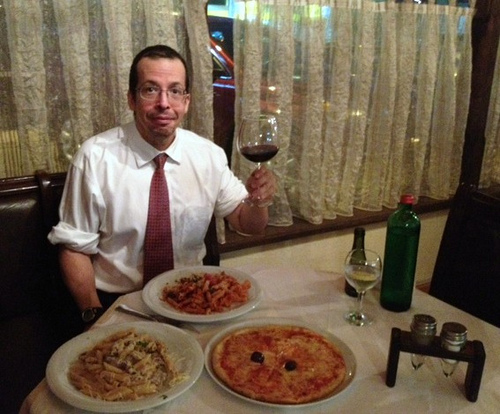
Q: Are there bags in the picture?
A: No, there are no bags.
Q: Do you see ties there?
A: Yes, there is a tie.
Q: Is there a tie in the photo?
A: Yes, there is a tie.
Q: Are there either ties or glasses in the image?
A: Yes, there is a tie.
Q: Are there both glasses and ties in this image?
A: Yes, there are both a tie and glasses.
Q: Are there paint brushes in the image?
A: No, there are no paint brushes.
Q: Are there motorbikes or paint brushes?
A: No, there are no paint brushes or motorbikes.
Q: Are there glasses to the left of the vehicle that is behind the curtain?
A: Yes, there are glasses to the left of the car.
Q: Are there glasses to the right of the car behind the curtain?
A: No, the glasses are to the left of the car.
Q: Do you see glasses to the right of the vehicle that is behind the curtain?
A: No, the glasses are to the left of the car.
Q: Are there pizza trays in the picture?
A: No, there are no pizza trays.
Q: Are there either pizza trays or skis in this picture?
A: No, there are no pizza trays or skis.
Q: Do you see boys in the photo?
A: No, there are no boys.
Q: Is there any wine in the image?
A: Yes, there is wine.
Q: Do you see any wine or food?
A: Yes, there is wine.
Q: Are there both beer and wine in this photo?
A: No, there is wine but no beer.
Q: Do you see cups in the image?
A: No, there are no cups.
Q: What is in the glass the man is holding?
A: The wine is in the glass.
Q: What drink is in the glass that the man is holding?
A: The drink is wine.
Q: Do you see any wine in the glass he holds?
A: Yes, there is wine in the glass.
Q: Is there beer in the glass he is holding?
A: No, there is wine in the glass.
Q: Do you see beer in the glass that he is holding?
A: No, there is wine in the glass.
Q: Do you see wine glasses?
A: Yes, there is a wine glass.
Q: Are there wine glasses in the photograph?
A: Yes, there is a wine glass.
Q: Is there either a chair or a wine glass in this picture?
A: Yes, there is a wine glass.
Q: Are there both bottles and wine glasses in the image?
A: Yes, there are both a wine glass and a bottle.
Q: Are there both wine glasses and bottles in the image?
A: Yes, there are both a wine glass and a bottle.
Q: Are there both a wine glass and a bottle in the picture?
A: Yes, there are both a wine glass and a bottle.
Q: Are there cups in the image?
A: No, there are no cups.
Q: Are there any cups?
A: No, there are no cups.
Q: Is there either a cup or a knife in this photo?
A: No, there are no cups or knives.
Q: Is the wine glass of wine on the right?
A: Yes, the wineglass is on the right of the image.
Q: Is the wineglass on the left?
A: No, the wineglass is on the right of the image.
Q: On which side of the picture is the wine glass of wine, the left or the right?
A: The wine glass is on the right of the image.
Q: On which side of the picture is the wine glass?
A: The wine glass is on the right of the image.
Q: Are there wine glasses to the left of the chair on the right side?
A: Yes, there is a wine glass to the left of the chair.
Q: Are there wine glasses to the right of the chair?
A: No, the wine glass is to the left of the chair.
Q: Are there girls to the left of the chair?
A: No, there is a wine glass to the left of the chair.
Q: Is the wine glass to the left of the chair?
A: Yes, the wine glass is to the left of the chair.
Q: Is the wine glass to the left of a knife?
A: No, the wine glass is to the left of the chair.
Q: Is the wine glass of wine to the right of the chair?
A: No, the wine glass is to the left of the chair.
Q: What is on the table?
A: The wine glass is on the table.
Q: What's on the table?
A: The wine glass is on the table.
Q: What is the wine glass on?
A: The wine glass is on the table.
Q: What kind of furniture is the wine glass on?
A: The wine glass is on the table.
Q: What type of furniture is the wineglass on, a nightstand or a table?
A: The wineglass is on a table.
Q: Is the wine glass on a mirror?
A: No, the wine glass is on the table.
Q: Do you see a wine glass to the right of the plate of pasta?
A: Yes, there is a wine glass to the right of the plate.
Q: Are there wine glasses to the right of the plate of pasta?
A: Yes, there is a wine glass to the right of the plate.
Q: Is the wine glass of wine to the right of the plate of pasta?
A: Yes, the wine glass is to the right of the plate.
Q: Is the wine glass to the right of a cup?
A: No, the wine glass is to the right of the plate.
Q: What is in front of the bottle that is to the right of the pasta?
A: The wine glass is in front of the bottle.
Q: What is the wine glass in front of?
A: The wine glass is in front of the bottle.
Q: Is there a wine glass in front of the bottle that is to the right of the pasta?
A: Yes, there is a wine glass in front of the bottle.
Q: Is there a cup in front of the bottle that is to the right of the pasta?
A: No, there is a wine glass in front of the bottle.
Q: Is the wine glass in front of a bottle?
A: Yes, the wine glass is in front of a bottle.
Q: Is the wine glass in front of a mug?
A: No, the wine glass is in front of a bottle.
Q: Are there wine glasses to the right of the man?
A: Yes, there is a wine glass to the right of the man.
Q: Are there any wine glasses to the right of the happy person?
A: Yes, there is a wine glass to the right of the man.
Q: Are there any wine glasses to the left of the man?
A: No, the wine glass is to the right of the man.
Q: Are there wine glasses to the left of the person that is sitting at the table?
A: No, the wine glass is to the right of the man.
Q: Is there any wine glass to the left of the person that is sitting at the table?
A: No, the wine glass is to the right of the man.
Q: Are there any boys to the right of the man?
A: No, there is a wine glass to the right of the man.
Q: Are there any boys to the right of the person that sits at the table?
A: No, there is a wine glass to the right of the man.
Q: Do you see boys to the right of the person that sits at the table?
A: No, there is a wine glass to the right of the man.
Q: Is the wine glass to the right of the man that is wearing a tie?
A: Yes, the wine glass is to the right of the man.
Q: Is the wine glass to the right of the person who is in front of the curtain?
A: Yes, the wine glass is to the right of the man.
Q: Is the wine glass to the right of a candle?
A: No, the wine glass is to the right of the man.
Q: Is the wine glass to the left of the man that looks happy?
A: No, the wine glass is to the right of the man.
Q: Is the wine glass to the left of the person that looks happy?
A: No, the wine glass is to the right of the man.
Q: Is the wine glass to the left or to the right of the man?
A: The wine glass is to the right of the man.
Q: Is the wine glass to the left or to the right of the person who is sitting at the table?
A: The wine glass is to the right of the man.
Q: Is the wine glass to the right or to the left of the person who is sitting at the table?
A: The wine glass is to the right of the man.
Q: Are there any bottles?
A: Yes, there is a bottle.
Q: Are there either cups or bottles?
A: Yes, there is a bottle.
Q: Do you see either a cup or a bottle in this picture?
A: Yes, there is a bottle.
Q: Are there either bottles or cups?
A: Yes, there is a bottle.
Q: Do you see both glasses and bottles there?
A: Yes, there are both a bottle and glasses.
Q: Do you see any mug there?
A: No, there are no mugs.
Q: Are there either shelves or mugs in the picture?
A: No, there are no mugs or shelves.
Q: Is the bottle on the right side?
A: Yes, the bottle is on the right of the image.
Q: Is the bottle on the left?
A: No, the bottle is on the right of the image.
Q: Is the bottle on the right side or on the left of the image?
A: The bottle is on the right of the image.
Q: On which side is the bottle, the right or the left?
A: The bottle is on the right of the image.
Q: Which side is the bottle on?
A: The bottle is on the right of the image.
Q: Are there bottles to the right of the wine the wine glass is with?
A: Yes, there is a bottle to the right of the wine.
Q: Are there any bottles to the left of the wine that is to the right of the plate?
A: No, the bottle is to the right of the wine.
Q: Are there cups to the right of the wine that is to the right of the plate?
A: No, there is a bottle to the right of the wine.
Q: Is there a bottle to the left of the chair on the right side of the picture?
A: Yes, there is a bottle to the left of the chair.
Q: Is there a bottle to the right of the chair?
A: No, the bottle is to the left of the chair.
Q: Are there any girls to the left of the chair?
A: No, there is a bottle to the left of the chair.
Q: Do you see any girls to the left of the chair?
A: No, there is a bottle to the left of the chair.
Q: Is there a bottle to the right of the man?
A: Yes, there is a bottle to the right of the man.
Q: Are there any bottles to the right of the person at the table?
A: Yes, there is a bottle to the right of the man.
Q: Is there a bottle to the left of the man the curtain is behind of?
A: No, the bottle is to the right of the man.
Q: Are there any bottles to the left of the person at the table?
A: No, the bottle is to the right of the man.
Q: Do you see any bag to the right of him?
A: No, there is a bottle to the right of the man.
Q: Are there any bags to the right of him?
A: No, there is a bottle to the right of the man.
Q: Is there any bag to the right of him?
A: No, there is a bottle to the right of the man.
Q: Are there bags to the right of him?
A: No, there is a bottle to the right of the man.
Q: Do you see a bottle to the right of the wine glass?
A: Yes, there is a bottle to the right of the wine glass.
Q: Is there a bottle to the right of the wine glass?
A: Yes, there is a bottle to the right of the wine glass.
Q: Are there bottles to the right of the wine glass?
A: Yes, there is a bottle to the right of the wine glass.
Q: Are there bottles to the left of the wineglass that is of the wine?
A: No, the bottle is to the right of the wine glass.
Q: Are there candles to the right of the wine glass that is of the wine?
A: No, there is a bottle to the right of the wine glass.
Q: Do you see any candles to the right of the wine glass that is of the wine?
A: No, there is a bottle to the right of the wine glass.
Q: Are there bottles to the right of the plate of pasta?
A: Yes, there is a bottle to the right of the plate.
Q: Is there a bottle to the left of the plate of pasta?
A: No, the bottle is to the right of the plate.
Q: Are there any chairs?
A: Yes, there is a chair.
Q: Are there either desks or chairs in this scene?
A: Yes, there is a chair.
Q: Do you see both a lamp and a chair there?
A: No, there is a chair but no lamps.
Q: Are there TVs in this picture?
A: No, there are no tvs.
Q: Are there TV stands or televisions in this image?
A: No, there are no televisions or TV stands.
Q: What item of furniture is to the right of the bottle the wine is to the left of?
A: The piece of furniture is a chair.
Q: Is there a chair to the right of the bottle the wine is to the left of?
A: Yes, there is a chair to the right of the bottle.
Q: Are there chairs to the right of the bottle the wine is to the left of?
A: Yes, there is a chair to the right of the bottle.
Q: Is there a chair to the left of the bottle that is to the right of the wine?
A: No, the chair is to the right of the bottle.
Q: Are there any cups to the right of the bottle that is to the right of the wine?
A: No, there is a chair to the right of the bottle.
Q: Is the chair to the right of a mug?
A: No, the chair is to the right of a bottle.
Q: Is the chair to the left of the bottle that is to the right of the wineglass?
A: No, the chair is to the right of the bottle.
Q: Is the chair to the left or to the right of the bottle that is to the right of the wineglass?
A: The chair is to the right of the bottle.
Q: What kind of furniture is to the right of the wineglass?
A: The piece of furniture is a chair.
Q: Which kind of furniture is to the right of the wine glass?
A: The piece of furniture is a chair.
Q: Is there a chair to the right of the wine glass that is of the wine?
A: Yes, there is a chair to the right of the wine glass.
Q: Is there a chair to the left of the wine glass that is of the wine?
A: No, the chair is to the right of the wine glass.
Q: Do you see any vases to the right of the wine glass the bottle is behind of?
A: No, there is a chair to the right of the wine glass.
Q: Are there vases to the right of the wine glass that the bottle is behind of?
A: No, there is a chair to the right of the wine glass.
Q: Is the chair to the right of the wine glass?
A: Yes, the chair is to the right of the wine glass.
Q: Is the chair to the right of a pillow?
A: No, the chair is to the right of the wine glass.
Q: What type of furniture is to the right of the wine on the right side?
A: The piece of furniture is a chair.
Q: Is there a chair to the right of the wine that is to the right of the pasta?
A: Yes, there is a chair to the right of the wine.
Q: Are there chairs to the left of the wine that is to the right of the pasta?
A: No, the chair is to the right of the wine.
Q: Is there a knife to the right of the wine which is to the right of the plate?
A: No, there is a chair to the right of the wine.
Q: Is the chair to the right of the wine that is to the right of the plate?
A: Yes, the chair is to the right of the wine.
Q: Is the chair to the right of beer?
A: No, the chair is to the right of the wine.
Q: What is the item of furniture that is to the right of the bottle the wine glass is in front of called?
A: The piece of furniture is a chair.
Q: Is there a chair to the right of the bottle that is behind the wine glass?
A: Yes, there is a chair to the right of the bottle.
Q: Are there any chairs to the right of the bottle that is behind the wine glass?
A: Yes, there is a chair to the right of the bottle.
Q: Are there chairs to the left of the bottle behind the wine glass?
A: No, the chair is to the right of the bottle.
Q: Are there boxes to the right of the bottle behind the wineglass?
A: No, there is a chair to the right of the bottle.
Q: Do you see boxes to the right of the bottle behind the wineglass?
A: No, there is a chair to the right of the bottle.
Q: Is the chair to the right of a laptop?
A: No, the chair is to the right of the bottle.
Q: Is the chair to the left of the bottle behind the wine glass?
A: No, the chair is to the right of the bottle.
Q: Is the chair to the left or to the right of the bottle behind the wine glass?
A: The chair is to the right of the bottle.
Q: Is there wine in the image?
A: Yes, there is wine.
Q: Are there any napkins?
A: No, there are no napkins.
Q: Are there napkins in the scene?
A: No, there are no napkins.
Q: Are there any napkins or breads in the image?
A: No, there are no napkins or breads.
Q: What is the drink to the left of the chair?
A: The drink is wine.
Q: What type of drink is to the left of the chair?
A: The drink is wine.